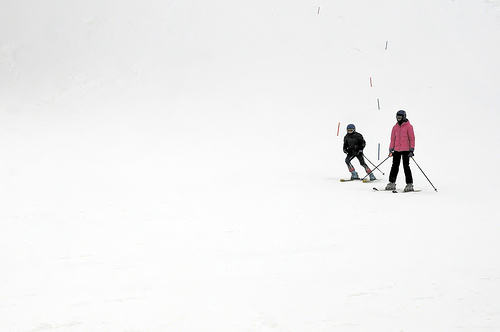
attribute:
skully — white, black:
[396, 110, 405, 120]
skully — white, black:
[347, 125, 355, 132]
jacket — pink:
[389, 119, 414, 152]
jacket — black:
[343, 132, 366, 153]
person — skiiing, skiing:
[386, 110, 415, 192]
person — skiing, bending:
[342, 124, 375, 180]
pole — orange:
[337, 121, 341, 135]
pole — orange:
[369, 77, 373, 87]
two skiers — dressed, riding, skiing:
[338, 110, 438, 193]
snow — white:
[1, 0, 500, 332]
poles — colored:
[317, 7, 389, 161]